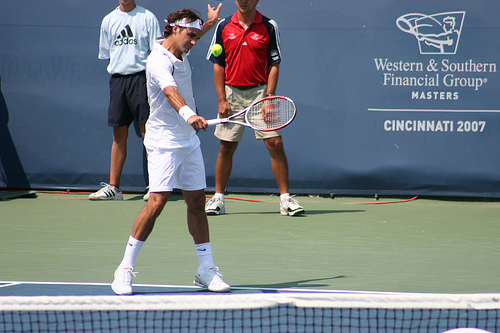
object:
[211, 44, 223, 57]
tennis ball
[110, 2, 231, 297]
male/tennis player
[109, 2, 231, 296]
professional/tennis player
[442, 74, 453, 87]
white letter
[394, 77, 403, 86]
white letter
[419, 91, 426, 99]
white letter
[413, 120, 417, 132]
white letter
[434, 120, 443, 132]
white letter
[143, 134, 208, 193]
white shorts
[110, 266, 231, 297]
white shoes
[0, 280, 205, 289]
white line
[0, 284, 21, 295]
dark blue/court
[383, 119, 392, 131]
white letter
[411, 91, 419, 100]
white letter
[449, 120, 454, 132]
white letter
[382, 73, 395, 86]
white letter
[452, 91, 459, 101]
white letter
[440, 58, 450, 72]
white letter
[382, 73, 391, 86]
white letter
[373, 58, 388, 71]
white letter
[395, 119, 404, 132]
white letter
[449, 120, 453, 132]
white letter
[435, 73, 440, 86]
white letter